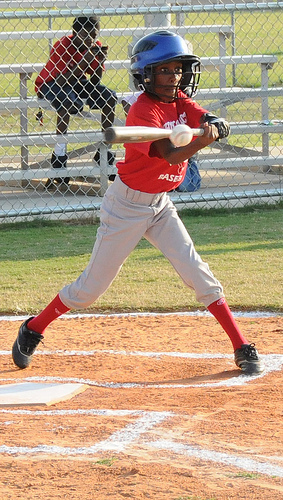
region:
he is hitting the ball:
[100, 125, 228, 142]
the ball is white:
[164, 122, 195, 148]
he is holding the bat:
[192, 117, 224, 144]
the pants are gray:
[111, 204, 124, 238]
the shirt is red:
[134, 151, 157, 176]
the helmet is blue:
[149, 33, 193, 60]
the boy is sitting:
[31, 57, 61, 104]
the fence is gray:
[11, 103, 51, 139]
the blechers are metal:
[209, 53, 247, 65]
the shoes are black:
[227, 340, 264, 373]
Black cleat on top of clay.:
[231, 346, 271, 377]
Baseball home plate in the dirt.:
[0, 379, 76, 410]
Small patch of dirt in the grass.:
[224, 467, 262, 481]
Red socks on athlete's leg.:
[206, 298, 247, 343]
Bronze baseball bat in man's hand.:
[106, 127, 162, 140]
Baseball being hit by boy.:
[170, 122, 198, 147]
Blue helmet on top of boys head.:
[129, 32, 209, 115]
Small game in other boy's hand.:
[88, 43, 107, 56]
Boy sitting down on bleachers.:
[53, 13, 114, 104]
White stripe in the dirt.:
[105, 426, 268, 484]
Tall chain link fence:
[198, 3, 277, 100]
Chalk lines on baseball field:
[80, 405, 194, 455]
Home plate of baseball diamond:
[0, 378, 88, 411]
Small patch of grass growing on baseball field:
[92, 454, 119, 470]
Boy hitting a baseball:
[98, 28, 226, 148]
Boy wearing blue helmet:
[130, 28, 201, 98]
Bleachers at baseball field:
[195, 24, 277, 66]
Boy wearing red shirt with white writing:
[114, 30, 232, 190]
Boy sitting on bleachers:
[33, 11, 115, 111]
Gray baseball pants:
[58, 180, 222, 308]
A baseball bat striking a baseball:
[105, 125, 229, 146]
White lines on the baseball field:
[3, 309, 282, 498]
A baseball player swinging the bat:
[11, 30, 258, 371]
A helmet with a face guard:
[130, 30, 200, 97]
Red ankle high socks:
[26, 293, 247, 351]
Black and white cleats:
[11, 316, 259, 370]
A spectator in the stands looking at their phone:
[36, 15, 116, 133]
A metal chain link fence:
[1, 1, 282, 222]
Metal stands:
[1, 0, 281, 187]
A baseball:
[170, 123, 192, 145]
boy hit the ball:
[109, 30, 214, 244]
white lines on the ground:
[83, 374, 146, 457]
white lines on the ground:
[155, 414, 239, 485]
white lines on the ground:
[105, 386, 202, 473]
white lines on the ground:
[141, 370, 235, 431]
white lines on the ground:
[57, 352, 235, 497]